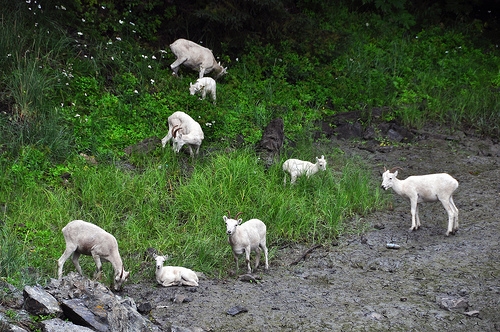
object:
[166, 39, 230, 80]
goat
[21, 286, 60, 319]
rock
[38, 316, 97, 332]
rock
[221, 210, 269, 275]
goat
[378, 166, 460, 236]
goat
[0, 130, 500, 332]
dirt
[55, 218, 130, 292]
goat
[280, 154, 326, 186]
goat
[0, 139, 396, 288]
grass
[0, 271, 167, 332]
rock pile